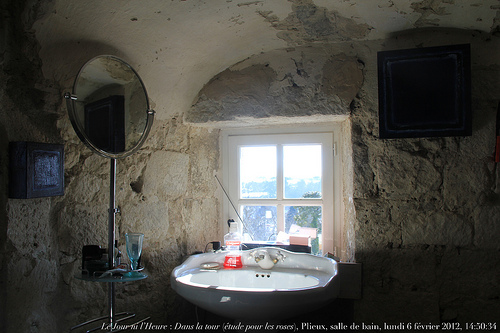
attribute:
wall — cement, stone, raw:
[0, 3, 497, 328]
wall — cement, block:
[357, 107, 492, 266]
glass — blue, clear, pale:
[121, 230, 148, 281]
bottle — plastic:
[218, 216, 247, 273]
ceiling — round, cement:
[142, 15, 497, 125]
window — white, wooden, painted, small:
[209, 116, 367, 263]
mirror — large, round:
[63, 52, 155, 159]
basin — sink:
[164, 240, 334, 325]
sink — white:
[171, 243, 346, 318]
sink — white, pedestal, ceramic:
[172, 247, 342, 321]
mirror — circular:
[71, 52, 148, 153]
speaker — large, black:
[371, 32, 467, 105]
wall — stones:
[0, 34, 497, 331]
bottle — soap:
[223, 220, 241, 267]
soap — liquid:
[230, 253, 241, 263]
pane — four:
[234, 147, 274, 200]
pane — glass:
[232, 142, 278, 200]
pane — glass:
[275, 142, 327, 202]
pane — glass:
[232, 200, 279, 245]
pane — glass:
[281, 205, 326, 256]